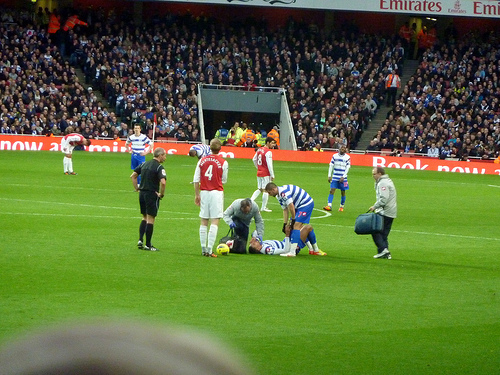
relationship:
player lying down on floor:
[250, 225, 325, 265] [227, 272, 288, 319]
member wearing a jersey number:
[193, 138, 229, 257] [193, 154, 229, 191]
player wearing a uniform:
[126, 122, 154, 192] [126, 135, 149, 168]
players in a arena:
[61, 123, 398, 260] [0, 0, 499, 374]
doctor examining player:
[221, 197, 261, 253] [251, 230, 291, 255]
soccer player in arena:
[193, 139, 229, 257] [0, 0, 497, 374]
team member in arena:
[250, 135, 276, 212] [0, 0, 497, 374]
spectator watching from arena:
[187, 58, 196, 69] [0, 0, 499, 374]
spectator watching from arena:
[275, 63, 284, 73] [0, 0, 499, 374]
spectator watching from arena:
[177, 78, 187, 93] [0, 0, 499, 374]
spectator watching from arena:
[361, 92, 376, 115] [0, 0, 499, 374]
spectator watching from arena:
[71, 107, 80, 117] [0, 0, 499, 374]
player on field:
[123, 145, 196, 251] [1, 147, 495, 372]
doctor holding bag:
[349, 164, 408, 263] [352, 209, 384, 236]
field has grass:
[1, 147, 495, 372] [23, 267, 490, 367]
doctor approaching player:
[354, 167, 397, 260] [249, 224, 327, 255]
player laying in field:
[249, 224, 327, 255] [1, 147, 495, 372]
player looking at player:
[264, 181, 318, 260] [243, 225, 325, 261]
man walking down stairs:
[385, 70, 401, 107] [350, 53, 421, 149]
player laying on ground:
[246, 224, 327, 259] [59, 268, 430, 308]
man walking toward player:
[365, 162, 400, 263] [242, 217, 329, 260]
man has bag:
[365, 162, 400, 263] [351, 206, 386, 238]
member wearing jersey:
[193, 138, 229, 257] [190, 151, 231, 190]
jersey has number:
[190, 151, 231, 190] [202, 162, 215, 182]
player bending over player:
[265, 182, 314, 257] [249, 224, 327, 255]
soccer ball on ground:
[212, 244, 234, 259] [253, 259, 499, 371]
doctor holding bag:
[354, 167, 397, 260] [345, 205, 400, 235]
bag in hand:
[345, 205, 400, 235] [361, 202, 383, 217]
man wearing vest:
[383, 67, 401, 109] [381, 73, 408, 88]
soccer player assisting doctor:
[193, 139, 229, 257] [223, 198, 265, 254]